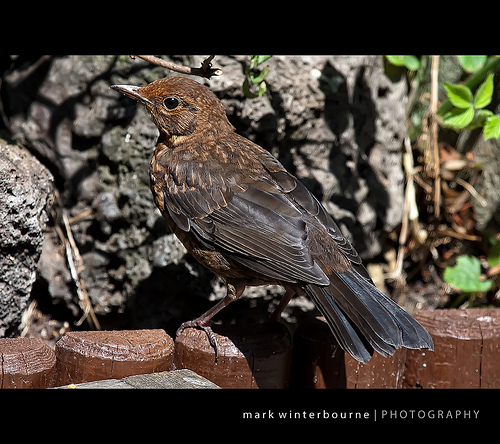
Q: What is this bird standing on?
A: Fence.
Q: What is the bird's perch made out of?
A: Wood.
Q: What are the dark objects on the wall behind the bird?
A: Shadows.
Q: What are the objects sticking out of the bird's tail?
A: Tail feathers.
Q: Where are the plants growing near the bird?
A: To the bird's right.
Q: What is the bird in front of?
A: Tree.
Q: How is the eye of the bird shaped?
A: Circle.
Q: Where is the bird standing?
A: On the wooden divider.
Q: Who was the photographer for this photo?
A: Mark Winterbourne.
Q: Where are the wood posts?
A: At the bottom of the picture.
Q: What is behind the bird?
A: Bark on a tree trunk.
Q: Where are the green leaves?
A: To the right in the background.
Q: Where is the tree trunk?
A: Behind the bird.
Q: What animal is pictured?
A: Bird.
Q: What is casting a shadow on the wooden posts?
A: The bird.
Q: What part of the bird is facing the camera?
A: The left back and tail.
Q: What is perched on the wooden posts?
A: A bird.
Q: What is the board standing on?
A: Brown wood post.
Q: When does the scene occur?
A: Daytime.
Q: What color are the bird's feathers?
A: Brown.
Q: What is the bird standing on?
A: A wooden fence.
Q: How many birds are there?
A: One.